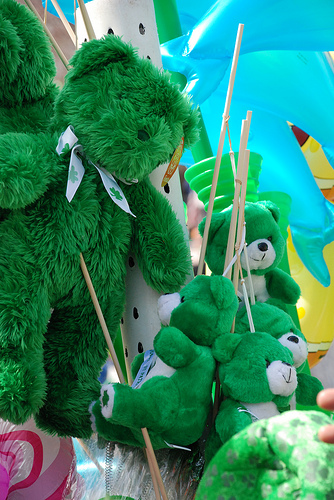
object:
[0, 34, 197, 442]
bear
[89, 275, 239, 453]
toys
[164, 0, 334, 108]
toys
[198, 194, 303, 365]
bears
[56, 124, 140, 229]
ribbon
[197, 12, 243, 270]
sticks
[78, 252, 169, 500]
stick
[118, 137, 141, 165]
mouth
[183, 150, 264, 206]
container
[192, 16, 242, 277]
pole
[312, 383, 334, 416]
fingers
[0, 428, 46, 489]
circle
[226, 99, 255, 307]
sticks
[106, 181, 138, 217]
tag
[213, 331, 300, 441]
toy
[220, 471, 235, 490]
spot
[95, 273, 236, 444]
animals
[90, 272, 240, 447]
bear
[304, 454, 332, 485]
clover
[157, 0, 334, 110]
whale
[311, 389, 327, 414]
fingertips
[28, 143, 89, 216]
bow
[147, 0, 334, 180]
background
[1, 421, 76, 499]
ballon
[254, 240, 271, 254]
snout